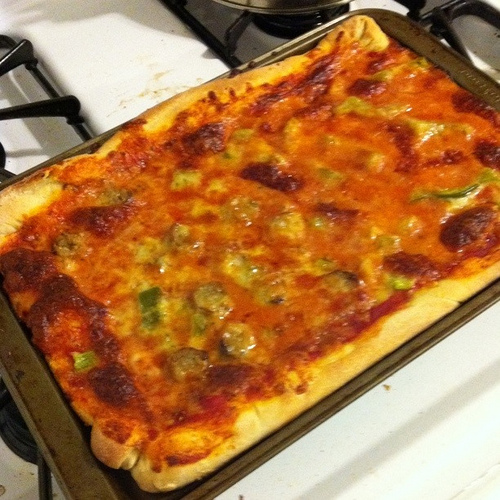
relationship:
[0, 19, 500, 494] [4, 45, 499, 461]
pizza has cheese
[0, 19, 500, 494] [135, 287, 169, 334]
pizza has pepper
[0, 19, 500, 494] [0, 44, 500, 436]
pizza has cheese and peppers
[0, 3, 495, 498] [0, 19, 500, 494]
pan has an egg casserole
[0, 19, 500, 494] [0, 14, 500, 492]
pizza has crust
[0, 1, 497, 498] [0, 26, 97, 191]
stove has burner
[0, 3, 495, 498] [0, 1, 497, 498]
pan on top of stove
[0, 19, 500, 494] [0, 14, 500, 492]
pizza has a crust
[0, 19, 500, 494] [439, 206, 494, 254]
pizza has brown bubble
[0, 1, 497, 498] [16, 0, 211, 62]
stove has a shadow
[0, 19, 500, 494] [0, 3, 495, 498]
pizza on top of pan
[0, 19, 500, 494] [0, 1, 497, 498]
pizza on top of stove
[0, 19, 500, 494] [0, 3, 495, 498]
food inside a pan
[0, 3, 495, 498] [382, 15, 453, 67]
pan has stains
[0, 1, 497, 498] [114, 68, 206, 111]
stove has crumbs